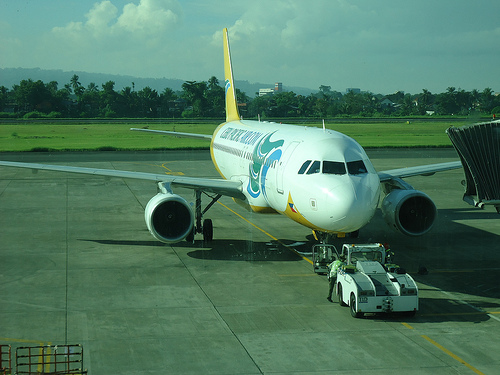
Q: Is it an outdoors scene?
A: Yes, it is outdoors.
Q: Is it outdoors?
A: Yes, it is outdoors.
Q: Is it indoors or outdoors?
A: It is outdoors.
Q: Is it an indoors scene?
A: No, it is outdoors.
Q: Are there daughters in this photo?
A: No, there are no daughters.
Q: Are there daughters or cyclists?
A: No, there are no daughters or cyclists.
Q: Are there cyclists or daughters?
A: No, there are no daughters or cyclists.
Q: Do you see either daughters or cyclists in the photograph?
A: No, there are no daughters or cyclists.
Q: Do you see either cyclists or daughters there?
A: No, there are no daughters or cyclists.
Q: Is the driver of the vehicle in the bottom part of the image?
A: Yes, the driver is in the bottom of the image.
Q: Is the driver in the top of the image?
A: No, the driver is in the bottom of the image.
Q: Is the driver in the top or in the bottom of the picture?
A: The driver is in the bottom of the image.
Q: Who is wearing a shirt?
A: The driver is wearing a shirt.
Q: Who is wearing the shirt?
A: The driver is wearing a shirt.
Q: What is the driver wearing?
A: The driver is wearing a shirt.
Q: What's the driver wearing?
A: The driver is wearing a shirt.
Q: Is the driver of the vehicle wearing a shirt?
A: Yes, the driver is wearing a shirt.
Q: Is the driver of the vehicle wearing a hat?
A: No, the driver is wearing a shirt.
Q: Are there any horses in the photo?
A: No, there are no horses.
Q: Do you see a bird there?
A: No, there are no birds.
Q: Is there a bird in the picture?
A: No, there are no birds.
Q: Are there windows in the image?
A: Yes, there is a window.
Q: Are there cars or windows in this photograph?
A: Yes, there is a window.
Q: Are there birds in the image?
A: No, there are no birds.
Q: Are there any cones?
A: No, there are no cones.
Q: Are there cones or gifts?
A: No, there are no cones or gifts.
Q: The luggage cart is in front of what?
A: The luggage cart is in front of the airplane.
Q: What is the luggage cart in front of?
A: The luggage cart is in front of the airplane.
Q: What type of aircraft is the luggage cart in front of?
A: The luggage cart is in front of the plane.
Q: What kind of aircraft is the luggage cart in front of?
A: The luggage cart is in front of the plane.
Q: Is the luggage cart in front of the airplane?
A: Yes, the luggage cart is in front of the airplane.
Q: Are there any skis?
A: No, there are no skis.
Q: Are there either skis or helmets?
A: No, there are no skis or helmets.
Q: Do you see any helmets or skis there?
A: No, there are no skis or helmets.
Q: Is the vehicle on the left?
A: No, the vehicle is on the right of the image.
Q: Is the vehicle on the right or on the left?
A: The vehicle is on the right of the image.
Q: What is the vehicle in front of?
A: The vehicle is in front of the airplane.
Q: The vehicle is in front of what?
A: The vehicle is in front of the airplane.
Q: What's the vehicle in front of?
A: The vehicle is in front of the airplane.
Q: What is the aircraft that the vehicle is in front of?
A: The aircraft is an airplane.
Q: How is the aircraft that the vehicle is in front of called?
A: The aircraft is an airplane.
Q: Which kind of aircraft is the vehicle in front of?
A: The vehicle is in front of the airplane.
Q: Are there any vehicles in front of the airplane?
A: Yes, there is a vehicle in front of the airplane.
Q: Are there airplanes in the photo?
A: Yes, there is an airplane.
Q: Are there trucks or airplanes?
A: Yes, there is an airplane.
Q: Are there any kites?
A: No, there are no kites.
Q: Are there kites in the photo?
A: No, there are no kites.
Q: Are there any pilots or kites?
A: No, there are no kites or pilots.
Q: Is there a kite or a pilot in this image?
A: No, there are no kites or pilots.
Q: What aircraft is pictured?
A: The aircraft is an airplane.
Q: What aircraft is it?
A: The aircraft is an airplane.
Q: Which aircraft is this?
A: This is an airplane.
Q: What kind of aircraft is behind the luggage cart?
A: The aircraft is an airplane.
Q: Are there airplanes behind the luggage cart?
A: Yes, there is an airplane behind the luggage cart.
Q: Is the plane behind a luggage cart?
A: Yes, the plane is behind a luggage cart.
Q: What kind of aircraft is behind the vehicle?
A: The aircraft is an airplane.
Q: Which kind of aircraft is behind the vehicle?
A: The aircraft is an airplane.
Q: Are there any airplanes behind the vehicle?
A: Yes, there is an airplane behind the vehicle.